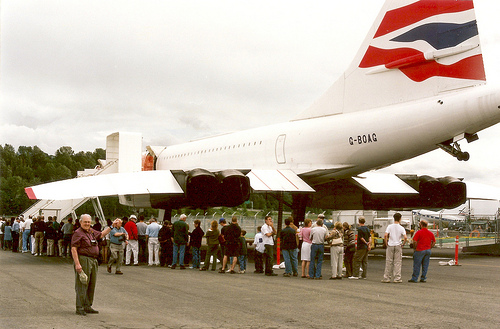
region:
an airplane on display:
[20, 0, 498, 227]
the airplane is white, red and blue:
[22, 2, 498, 219]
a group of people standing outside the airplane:
[0, 204, 467, 315]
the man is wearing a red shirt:
[405, 223, 437, 253]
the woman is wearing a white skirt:
[294, 237, 315, 264]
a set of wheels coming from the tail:
[428, 125, 486, 166]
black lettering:
[340, 122, 391, 158]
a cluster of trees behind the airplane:
[0, 138, 472, 223]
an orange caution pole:
[449, 227, 465, 269]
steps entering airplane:
[10, 150, 120, 241]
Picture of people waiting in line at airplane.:
[30, 0, 485, 310]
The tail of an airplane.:
[315, 0, 490, 90]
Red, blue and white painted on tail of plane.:
[345, 0, 490, 85]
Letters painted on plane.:
[340, 125, 385, 150]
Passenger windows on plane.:
[170, 136, 270, 152]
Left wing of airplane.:
[15, 160, 175, 200]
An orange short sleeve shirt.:
[405, 212, 438, 260]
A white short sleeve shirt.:
[385, 218, 405, 250]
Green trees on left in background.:
[0, 138, 56, 208]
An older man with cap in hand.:
[65, 207, 112, 327]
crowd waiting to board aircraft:
[9, 189, 449, 279]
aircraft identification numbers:
[340, 128, 389, 150]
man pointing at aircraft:
[64, 211, 116, 318]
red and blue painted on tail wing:
[355, 1, 499, 96]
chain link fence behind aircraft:
[413, 191, 498, 264]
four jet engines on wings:
[183, 169, 464, 221]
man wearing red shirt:
[411, 211, 452, 296]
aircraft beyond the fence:
[400, 198, 484, 243]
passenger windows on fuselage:
[161, 133, 294, 164]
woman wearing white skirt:
[299, 213, 318, 265]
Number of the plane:
[339, 132, 396, 148]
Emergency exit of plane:
[267, 139, 297, 170]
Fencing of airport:
[478, 194, 499, 256]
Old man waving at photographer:
[72, 211, 125, 327]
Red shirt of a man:
[412, 224, 445, 253]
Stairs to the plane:
[13, 176, 95, 225]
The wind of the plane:
[33, 172, 332, 198]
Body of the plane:
[153, 123, 496, 140]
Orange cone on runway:
[444, 239, 472, 273]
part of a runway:
[302, 277, 367, 326]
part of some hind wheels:
[437, 134, 478, 158]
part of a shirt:
[78, 245, 95, 260]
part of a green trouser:
[85, 255, 100, 277]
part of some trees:
[10, 152, 57, 178]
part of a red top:
[421, 232, 431, 247]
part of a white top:
[392, 224, 399, 246]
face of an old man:
[81, 212, 93, 229]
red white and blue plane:
[39, 23, 496, 160]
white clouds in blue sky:
[17, 49, 64, 82]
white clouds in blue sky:
[154, 31, 195, 60]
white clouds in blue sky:
[140, 71, 191, 97]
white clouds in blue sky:
[191, 41, 232, 71]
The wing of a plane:
[11, 155, 321, 206]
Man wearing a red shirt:
[402, 212, 439, 253]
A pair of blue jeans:
[301, 235, 327, 280]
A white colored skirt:
[292, 235, 317, 265]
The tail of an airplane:
[280, 0, 491, 120]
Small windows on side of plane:
[150, 130, 270, 160]